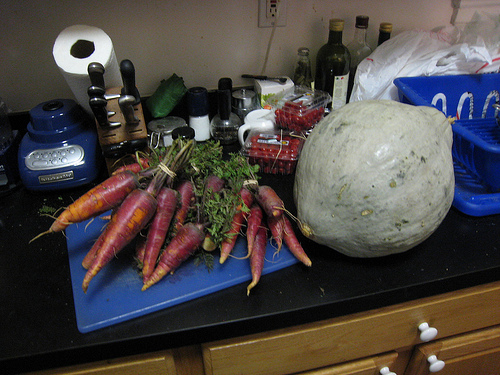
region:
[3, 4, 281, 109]
the wall is white.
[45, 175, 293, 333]
The cutting board is blue.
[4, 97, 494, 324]
The counter is black.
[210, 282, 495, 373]
The drawers are brown.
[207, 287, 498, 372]
the drawers are wooden.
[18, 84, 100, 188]
The blender is blue.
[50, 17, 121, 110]
the paper towel is white.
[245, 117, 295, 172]
The tomatoes are red.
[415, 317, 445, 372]
The knobs are white.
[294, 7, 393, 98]
The bottles are glass.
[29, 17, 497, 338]
a scene in a kitchen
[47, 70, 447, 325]
the countertop is black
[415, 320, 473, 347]
the drawer pull is white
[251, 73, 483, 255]
a large grey gourd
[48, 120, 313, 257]
the carrots are purple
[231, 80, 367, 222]
two packs of tomatoes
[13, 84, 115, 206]
the bottom of a blender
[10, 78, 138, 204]
the blender is blue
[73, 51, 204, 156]
there are five knives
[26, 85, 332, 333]
the cutting board is blue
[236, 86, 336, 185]
Two containers of tomatoes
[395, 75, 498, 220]
Plastic blue dish rack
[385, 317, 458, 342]
White knob on wooden drawer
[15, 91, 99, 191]
Blue blender base on counter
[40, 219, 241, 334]
Blue cutting board on counter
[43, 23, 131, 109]
Roll of paper towels near wall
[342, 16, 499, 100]
Plastic grocery bags behind dish racks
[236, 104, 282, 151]
white mug on counter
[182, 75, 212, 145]
Salt shaker with black top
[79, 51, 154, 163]
Five knifes in knife rack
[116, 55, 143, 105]
a black knife handle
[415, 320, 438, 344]
a white knob on the drawer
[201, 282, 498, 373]
a brown wooden door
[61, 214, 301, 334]
a blue cutting board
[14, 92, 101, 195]
the blue base of a blender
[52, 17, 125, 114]
a white roll of toilet paper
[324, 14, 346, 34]
a bottle cap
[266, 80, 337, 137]
a clear plastic container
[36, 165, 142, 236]
an orange and purple carrot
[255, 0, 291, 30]
an electrical socket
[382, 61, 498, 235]
The dish drainer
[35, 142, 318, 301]
The vegetables on the blue cutting board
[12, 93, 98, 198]
The base of the blue blender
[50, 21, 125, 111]
The roll of paper towels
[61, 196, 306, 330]
The blue cutting board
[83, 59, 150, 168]
The block of knives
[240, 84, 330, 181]
The boxes of cherry tomatoes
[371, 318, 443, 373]
The white handles on the cupboards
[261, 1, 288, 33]
The electrical outlet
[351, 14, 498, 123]
The white plastic bags